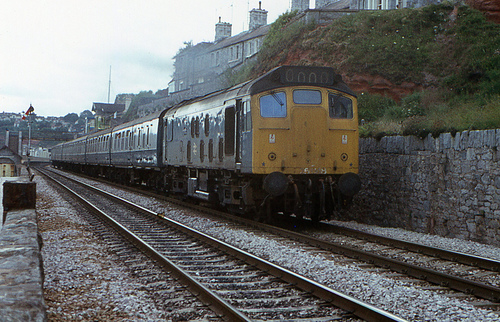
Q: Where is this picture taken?
A: A railway.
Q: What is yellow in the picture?
A: The train's front.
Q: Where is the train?
A: On the train tracks.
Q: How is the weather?
A: Overcast.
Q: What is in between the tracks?
A: Gravel.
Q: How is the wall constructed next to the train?
A: Of stone.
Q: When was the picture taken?
A: Early evening.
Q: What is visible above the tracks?
A: Buildings.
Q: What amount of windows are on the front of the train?
A: Three.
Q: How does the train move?
A: Rail wheels.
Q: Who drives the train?
A: Conductor.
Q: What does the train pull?
A: Train cars.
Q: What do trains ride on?
A: Tracks.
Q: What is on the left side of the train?
A: Wall.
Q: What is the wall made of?
A: Rock.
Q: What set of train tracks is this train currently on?
A: Tracks on the right.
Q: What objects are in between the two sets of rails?
A: Gravel.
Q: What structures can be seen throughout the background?
A: Houses.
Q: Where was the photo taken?
A: Outdoors near a train.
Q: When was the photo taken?
A: Daytime.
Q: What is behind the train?
A: A wall.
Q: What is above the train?
A: Buildings.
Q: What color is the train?
A: Gold and black.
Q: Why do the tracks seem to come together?
A: Perspective of the photo.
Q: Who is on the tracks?
A: No one.